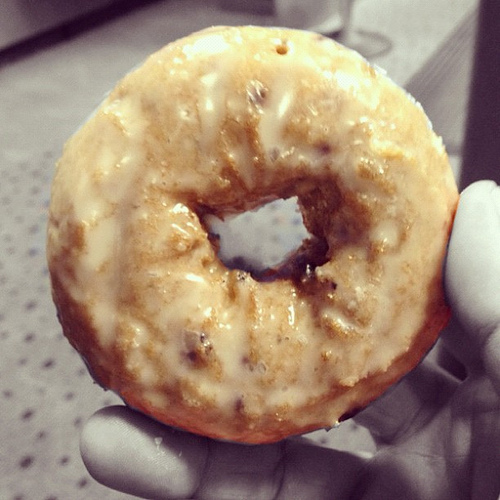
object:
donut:
[47, 25, 459, 446]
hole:
[203, 195, 315, 270]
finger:
[80, 405, 373, 499]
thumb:
[442, 180, 500, 394]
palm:
[351, 378, 500, 498]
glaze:
[47, 26, 460, 445]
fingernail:
[488, 181, 500, 216]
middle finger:
[206, 216, 464, 440]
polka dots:
[0, 147, 360, 499]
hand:
[80, 179, 500, 498]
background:
[0, 1, 499, 499]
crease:
[187, 438, 211, 499]